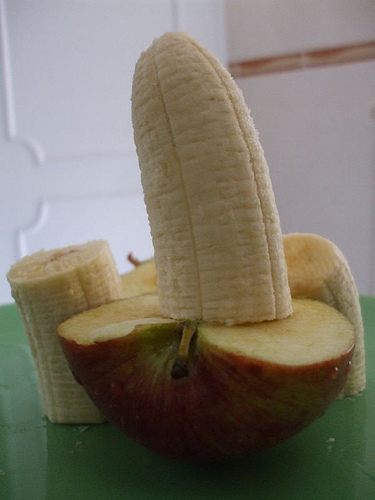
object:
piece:
[132, 30, 295, 322]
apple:
[58, 284, 357, 471]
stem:
[171, 326, 199, 381]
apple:
[119, 259, 162, 298]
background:
[4, 0, 374, 373]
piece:
[7, 236, 124, 440]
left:
[171, 5, 375, 497]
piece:
[281, 230, 371, 399]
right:
[0, 0, 219, 495]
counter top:
[1, 292, 374, 493]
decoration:
[223, 34, 374, 89]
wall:
[5, 3, 233, 300]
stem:
[127, 247, 144, 269]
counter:
[6, 290, 374, 492]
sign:
[223, 36, 374, 82]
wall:
[218, 0, 374, 294]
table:
[7, 293, 373, 494]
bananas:
[284, 231, 369, 403]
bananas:
[127, 35, 294, 326]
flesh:
[58, 282, 353, 363]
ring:
[178, 323, 198, 357]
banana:
[8, 240, 120, 428]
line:
[148, 42, 190, 308]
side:
[138, 46, 276, 319]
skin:
[65, 353, 347, 462]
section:
[10, 238, 126, 435]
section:
[279, 230, 366, 405]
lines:
[215, 38, 282, 319]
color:
[134, 321, 202, 383]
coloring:
[101, 361, 296, 443]